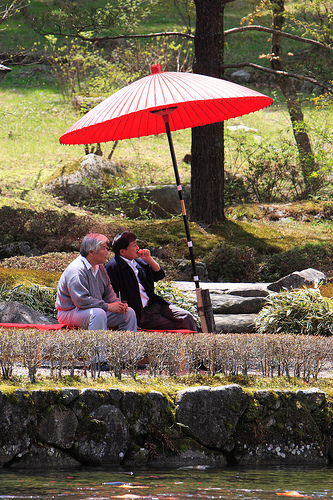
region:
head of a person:
[80, 226, 116, 265]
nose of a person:
[100, 246, 111, 254]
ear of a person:
[87, 245, 98, 254]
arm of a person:
[66, 279, 106, 310]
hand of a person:
[110, 296, 125, 310]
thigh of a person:
[53, 306, 94, 345]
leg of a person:
[87, 318, 119, 357]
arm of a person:
[138, 243, 165, 271]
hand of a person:
[136, 242, 158, 260]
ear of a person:
[118, 246, 130, 259]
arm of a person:
[85, 291, 126, 310]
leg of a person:
[81, 312, 109, 347]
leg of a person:
[118, 317, 146, 356]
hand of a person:
[114, 300, 133, 314]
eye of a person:
[91, 245, 109, 254]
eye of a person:
[128, 235, 143, 249]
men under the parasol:
[59, 218, 194, 328]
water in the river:
[141, 479, 162, 489]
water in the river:
[191, 481, 214, 495]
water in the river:
[248, 478, 262, 487]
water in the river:
[53, 481, 67, 489]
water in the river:
[134, 483, 149, 498]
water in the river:
[285, 470, 305, 485]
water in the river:
[233, 470, 258, 486]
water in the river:
[189, 483, 203, 493]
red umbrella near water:
[70, 73, 256, 148]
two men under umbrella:
[34, 219, 202, 350]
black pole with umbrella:
[146, 117, 213, 336]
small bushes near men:
[0, 328, 310, 369]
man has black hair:
[101, 232, 130, 260]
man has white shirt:
[106, 259, 159, 310]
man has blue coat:
[104, 252, 163, 306]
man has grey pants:
[146, 299, 193, 334]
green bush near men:
[263, 282, 331, 335]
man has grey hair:
[77, 229, 106, 256]